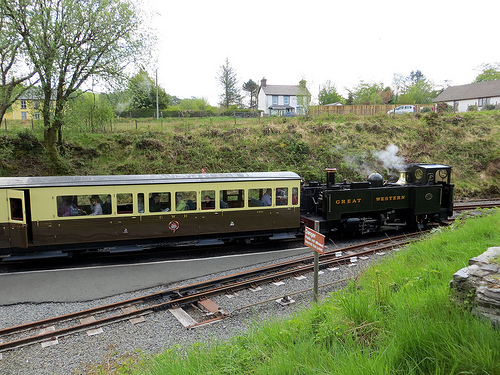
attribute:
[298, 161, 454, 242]
engine train — black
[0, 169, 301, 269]
passenger car — yellow, brown, small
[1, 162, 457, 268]
train — small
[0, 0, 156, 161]
tree — green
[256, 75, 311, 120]
house — in the distance, white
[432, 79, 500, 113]
house — in the distance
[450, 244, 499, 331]
rock — large, beside train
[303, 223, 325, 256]
sign — red, white, small, brown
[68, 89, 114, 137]
tree — green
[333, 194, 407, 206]
great western — on side of train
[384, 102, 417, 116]
car — silver, parked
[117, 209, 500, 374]
grass — tall, beside train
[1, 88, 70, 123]
house — in the distance